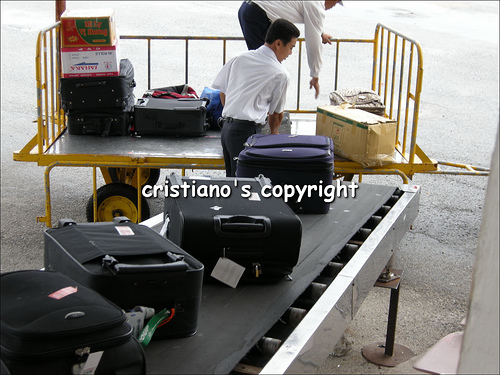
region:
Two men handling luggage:
[187, 0, 382, 193]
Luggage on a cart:
[25, 15, 457, 182]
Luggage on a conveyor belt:
[2, 125, 464, 372]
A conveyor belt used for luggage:
[8, 110, 444, 374]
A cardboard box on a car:
[302, 82, 419, 179]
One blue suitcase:
[227, 112, 357, 209]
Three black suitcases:
[2, 145, 319, 372]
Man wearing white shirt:
[215, 15, 313, 175]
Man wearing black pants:
[192, 0, 327, 172]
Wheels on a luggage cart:
[52, 125, 177, 268]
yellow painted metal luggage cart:
[10, 18, 485, 226]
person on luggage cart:
[235, 0, 340, 100]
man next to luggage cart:
[210, 15, 300, 180]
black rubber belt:
[136, 172, 396, 372]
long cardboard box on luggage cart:
[315, 97, 395, 167]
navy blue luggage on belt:
[232, 130, 333, 216]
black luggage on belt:
[160, 170, 300, 282]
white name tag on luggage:
[206, 252, 242, 287]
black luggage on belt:
[42, 212, 197, 342]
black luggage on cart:
[131, 90, 206, 137]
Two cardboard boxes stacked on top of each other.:
[53, 3, 123, 80]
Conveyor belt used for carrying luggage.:
[306, 215, 384, 288]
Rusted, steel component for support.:
[365, 260, 417, 365]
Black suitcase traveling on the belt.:
[43, 214, 206, 346]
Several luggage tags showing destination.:
[127, 302, 181, 344]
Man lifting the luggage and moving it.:
[201, 12, 303, 162]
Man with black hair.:
[261, 18, 301, 62]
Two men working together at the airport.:
[215, 0, 361, 172]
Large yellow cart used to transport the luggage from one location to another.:
[21, 27, 440, 186]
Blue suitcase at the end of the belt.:
[230, 130, 339, 212]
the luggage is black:
[156, 277, 167, 294]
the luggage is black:
[147, 287, 166, 307]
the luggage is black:
[144, 268, 160, 304]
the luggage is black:
[160, 281, 177, 304]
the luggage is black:
[140, 267, 155, 293]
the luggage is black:
[156, 282, 171, 309]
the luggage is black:
[132, 283, 148, 296]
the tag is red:
[62, 284, 73, 296]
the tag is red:
[59, 288, 65, 297]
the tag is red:
[62, 286, 73, 304]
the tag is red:
[52, 283, 94, 318]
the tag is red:
[55, 285, 67, 300]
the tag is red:
[56, 290, 77, 306]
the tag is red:
[49, 283, 74, 299]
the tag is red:
[66, 293, 73, 303]